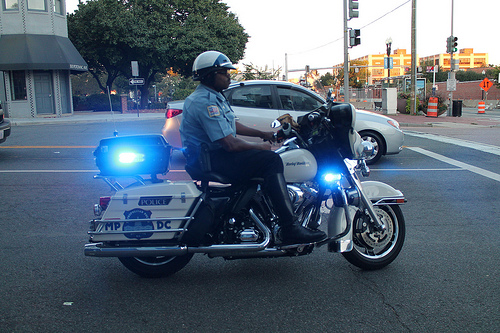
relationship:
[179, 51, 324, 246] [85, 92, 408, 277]
cop on motorcycle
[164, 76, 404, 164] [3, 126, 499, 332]
car in street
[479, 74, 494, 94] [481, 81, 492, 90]
sign with arrows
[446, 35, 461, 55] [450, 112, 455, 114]
trafficlight on a pole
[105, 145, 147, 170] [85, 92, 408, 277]
blue light on motorcycle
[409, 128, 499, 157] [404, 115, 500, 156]
line of a crosswalk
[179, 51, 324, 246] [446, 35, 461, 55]
cop waits for trafficlight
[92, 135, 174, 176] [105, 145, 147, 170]
trunk case has a blue light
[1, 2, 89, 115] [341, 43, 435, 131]
apartment on corner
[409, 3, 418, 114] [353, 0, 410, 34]
pole for power line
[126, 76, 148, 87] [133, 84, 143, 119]
one way on a post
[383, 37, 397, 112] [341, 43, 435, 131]
streetlight on corner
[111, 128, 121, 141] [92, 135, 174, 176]
knob on trunk case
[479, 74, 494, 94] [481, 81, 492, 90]
sign has two arrows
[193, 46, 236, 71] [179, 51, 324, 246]
helmet on cop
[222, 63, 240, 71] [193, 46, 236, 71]
visor on helmet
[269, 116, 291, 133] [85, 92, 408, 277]
side mirror on motorcycle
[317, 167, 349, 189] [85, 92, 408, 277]
blue light on front of motorcycle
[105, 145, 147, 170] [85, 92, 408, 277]
blue light in rear of motorcycle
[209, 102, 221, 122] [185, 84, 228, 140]
badge on shoulder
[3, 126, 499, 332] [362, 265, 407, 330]
street has a crack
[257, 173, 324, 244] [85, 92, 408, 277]
boot on motorcycle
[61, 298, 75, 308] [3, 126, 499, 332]
white spot on street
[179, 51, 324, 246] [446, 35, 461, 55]
cop waits for a trafficlight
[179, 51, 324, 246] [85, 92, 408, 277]
cop on h motorcycle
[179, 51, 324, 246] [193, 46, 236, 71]
cop wearing a white helmet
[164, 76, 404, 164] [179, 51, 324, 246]
car waiting beside a cop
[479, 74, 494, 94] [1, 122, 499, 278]
sign on street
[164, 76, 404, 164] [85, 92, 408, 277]
car and motorcycle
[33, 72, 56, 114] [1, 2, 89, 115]
door on apartment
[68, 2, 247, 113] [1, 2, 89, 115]
trees near apartment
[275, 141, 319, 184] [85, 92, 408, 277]
gas tank on motorcycle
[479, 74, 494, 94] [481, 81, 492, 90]
sign showing direction arrows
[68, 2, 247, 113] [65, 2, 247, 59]
trees with leaves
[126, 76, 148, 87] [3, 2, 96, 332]
one way points to left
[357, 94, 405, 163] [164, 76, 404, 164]
front of car